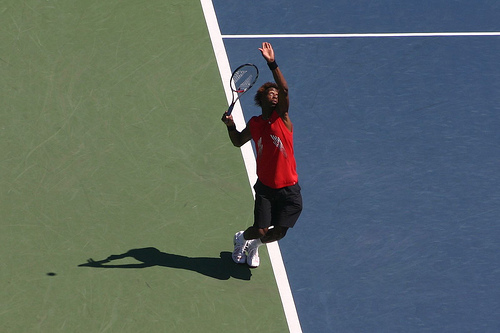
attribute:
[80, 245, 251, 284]
shadow — court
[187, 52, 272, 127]
racket — black, tennis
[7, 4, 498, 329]
court — tennis, green, blue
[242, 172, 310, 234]
shorts — black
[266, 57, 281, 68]
wristband — black, soft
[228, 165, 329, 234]
shorts — black, athletic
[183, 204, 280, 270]
shoes — white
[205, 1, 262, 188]
line — thick, white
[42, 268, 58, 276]
shadow — ball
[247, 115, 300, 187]
tank top — red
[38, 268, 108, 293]
ball — tennis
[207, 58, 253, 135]
racket — tennis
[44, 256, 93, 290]
ball — tennis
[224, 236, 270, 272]
shoes — tennis, white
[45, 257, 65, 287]
ball — tennis